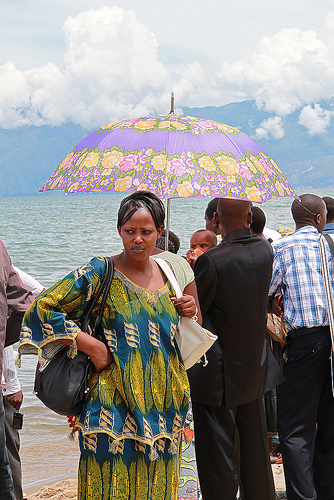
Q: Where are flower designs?
A: On the umbrella.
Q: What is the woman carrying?
A: Two bags.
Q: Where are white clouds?
A: In the sky.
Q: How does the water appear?
A: Calm.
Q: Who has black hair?
A: The woman.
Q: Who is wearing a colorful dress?
A: The woman.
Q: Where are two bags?
A: Over woman's shoulders.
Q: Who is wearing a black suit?
A: Man in the background.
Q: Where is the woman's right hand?
A: On woman's hip.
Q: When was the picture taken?
A: During the daytime.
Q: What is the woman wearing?
A: A dress.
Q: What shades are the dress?
A: Green and Blue.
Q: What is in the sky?
A: Clouds.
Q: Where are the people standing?
A: On the beach.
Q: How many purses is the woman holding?
A: Two.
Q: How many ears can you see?
A: Four.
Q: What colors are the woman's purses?
A: White and black.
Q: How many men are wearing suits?
A: One.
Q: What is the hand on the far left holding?
A: A camera.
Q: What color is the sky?
A: Blue.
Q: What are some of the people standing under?
A: Umbrella.